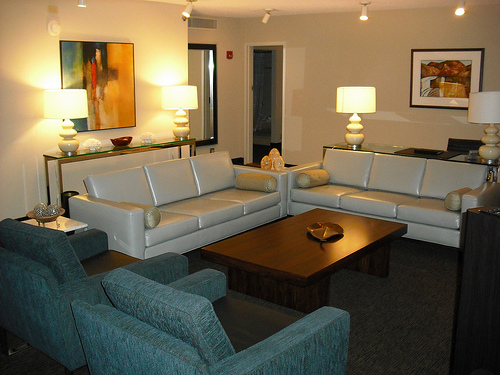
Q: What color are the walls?
A: White.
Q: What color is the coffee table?
A: Brown.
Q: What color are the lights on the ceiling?
A: White.